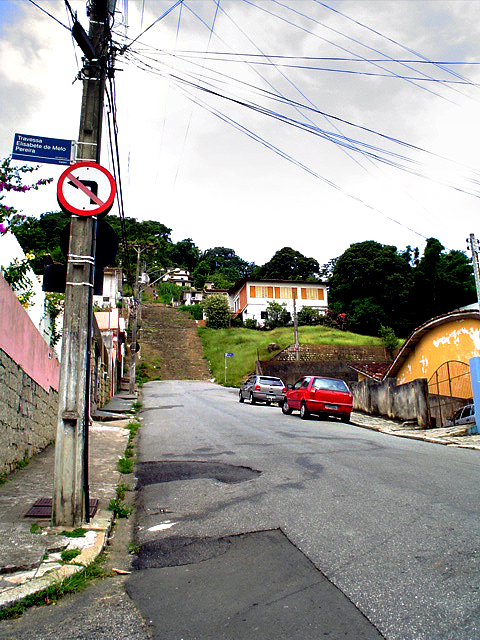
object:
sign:
[55, 223, 91, 478]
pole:
[53, 157, 97, 523]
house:
[230, 276, 328, 329]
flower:
[26, 252, 35, 260]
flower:
[0, 148, 53, 236]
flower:
[325, 309, 348, 329]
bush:
[160, 282, 326, 330]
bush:
[201, 293, 291, 331]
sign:
[13, 132, 75, 165]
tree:
[252, 247, 320, 281]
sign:
[57, 161, 117, 216]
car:
[282, 376, 353, 424]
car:
[239, 375, 287, 406]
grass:
[196, 325, 394, 387]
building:
[349, 300, 479, 414]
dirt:
[141, 303, 215, 381]